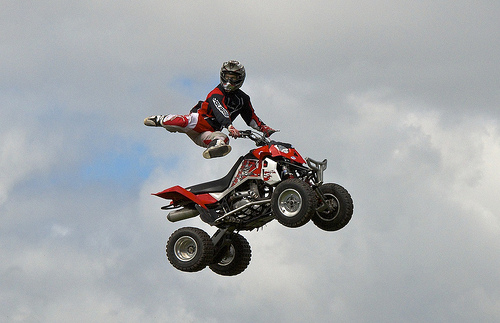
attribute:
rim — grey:
[276, 187, 303, 218]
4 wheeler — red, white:
[150, 129, 353, 275]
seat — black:
[183, 154, 245, 195]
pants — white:
[146, 104, 230, 158]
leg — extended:
[140, 107, 199, 135]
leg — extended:
[200, 131, 232, 158]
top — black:
[201, 87, 251, 124]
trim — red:
[163, 112, 188, 125]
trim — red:
[203, 138, 211, 144]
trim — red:
[221, 136, 231, 143]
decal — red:
[232, 158, 274, 188]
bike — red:
[156, 123, 356, 275]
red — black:
[250, 139, 300, 163]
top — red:
[192, 82, 257, 126]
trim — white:
[241, 161, 281, 184]